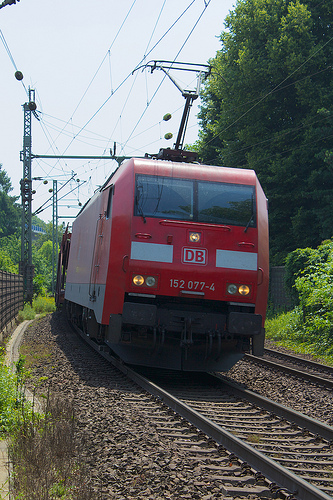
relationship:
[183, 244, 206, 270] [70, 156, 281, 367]
logo on train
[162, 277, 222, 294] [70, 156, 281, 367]
152 077-4 on train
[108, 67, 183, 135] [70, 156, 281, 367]
catenary over train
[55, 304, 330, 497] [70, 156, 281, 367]
rails are for train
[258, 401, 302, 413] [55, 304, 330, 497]
bed for rails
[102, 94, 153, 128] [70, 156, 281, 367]
pantograph over train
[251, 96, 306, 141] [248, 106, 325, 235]
leaves are on trees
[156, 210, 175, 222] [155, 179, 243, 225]
wiper on windshield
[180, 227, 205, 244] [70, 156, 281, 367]
headlamp on train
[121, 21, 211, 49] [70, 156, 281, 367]
wires are crossing above train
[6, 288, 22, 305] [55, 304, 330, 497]
fence on side of rails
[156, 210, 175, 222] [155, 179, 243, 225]
wiper attached to windshield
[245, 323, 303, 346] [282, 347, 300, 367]
grass near gravel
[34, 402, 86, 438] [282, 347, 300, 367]
dirt near gravel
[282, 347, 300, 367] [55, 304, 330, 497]
gravel under rails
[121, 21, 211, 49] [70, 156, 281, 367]
wires are above train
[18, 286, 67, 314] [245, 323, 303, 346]
bushes are in grass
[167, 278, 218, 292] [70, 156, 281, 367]
152 077-4 on train